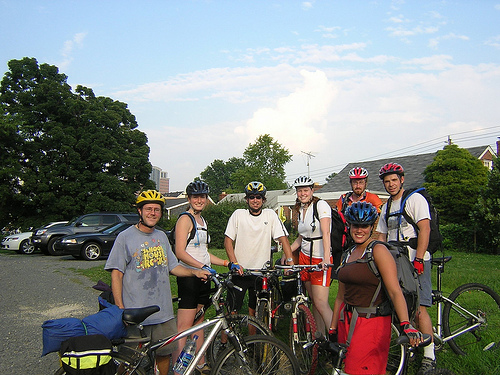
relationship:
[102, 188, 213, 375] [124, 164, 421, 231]
people are wearing helmets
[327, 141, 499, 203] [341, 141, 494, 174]
building has top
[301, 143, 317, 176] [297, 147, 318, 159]
telephone pole has top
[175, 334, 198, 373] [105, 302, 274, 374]
water bottle attached to bicycle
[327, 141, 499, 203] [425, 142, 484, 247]
house beside tree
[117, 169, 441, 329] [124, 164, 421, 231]
people are wearing helmets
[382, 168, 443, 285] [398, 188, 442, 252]
man wearing backpack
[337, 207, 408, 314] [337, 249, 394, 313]
young lady has tank top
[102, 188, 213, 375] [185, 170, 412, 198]
people are wearing a helmet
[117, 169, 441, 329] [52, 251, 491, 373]
people are holding bicycles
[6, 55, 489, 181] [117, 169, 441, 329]
trees are behind people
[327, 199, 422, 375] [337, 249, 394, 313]
young lady wearing brown tank top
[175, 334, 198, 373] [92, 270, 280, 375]
water bottle on bicycle